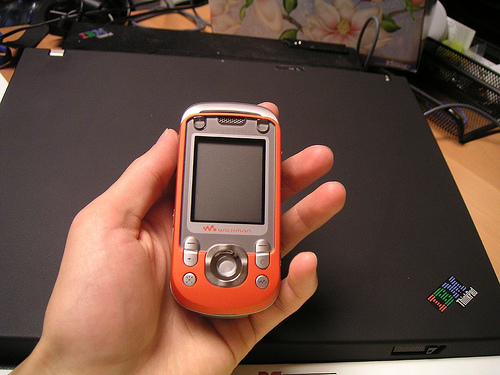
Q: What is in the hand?
A: An orange cell phone.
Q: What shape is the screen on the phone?
A: Rectangular.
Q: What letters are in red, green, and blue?
A: IBM.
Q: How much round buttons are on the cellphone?
A: Two.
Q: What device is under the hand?
A: A laptop.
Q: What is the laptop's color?
A: Black.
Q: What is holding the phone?
A: Hand.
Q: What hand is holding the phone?
A: Left.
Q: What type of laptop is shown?
A: IBM.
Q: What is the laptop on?
A: Table.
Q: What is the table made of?
A: Wood.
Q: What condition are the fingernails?
A: Short.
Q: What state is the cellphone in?
A: Powered off.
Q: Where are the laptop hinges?
A: Back of the image.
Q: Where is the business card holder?
A: Right side at the back of the laptop.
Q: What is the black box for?
A: Storage.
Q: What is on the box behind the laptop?
A: Flowers.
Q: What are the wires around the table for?
A: Notebook.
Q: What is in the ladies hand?
A: Orange cell phone.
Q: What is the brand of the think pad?
A: IBM.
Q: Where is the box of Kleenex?
A: Behind laptop.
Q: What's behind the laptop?
A: Bin.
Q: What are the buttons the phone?
A: Silver buttons.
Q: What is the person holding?
A: A cell phone.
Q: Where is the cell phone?
A: In the person's hand.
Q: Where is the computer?
A: On the desk.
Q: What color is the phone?
A: Orange.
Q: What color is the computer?
A: Black.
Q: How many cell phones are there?
A: One.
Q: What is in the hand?
A: A cell phone.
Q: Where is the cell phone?
A: In the hand.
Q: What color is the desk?
A: Brown.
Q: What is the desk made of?
A: Wood.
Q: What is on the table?
A: The computer.